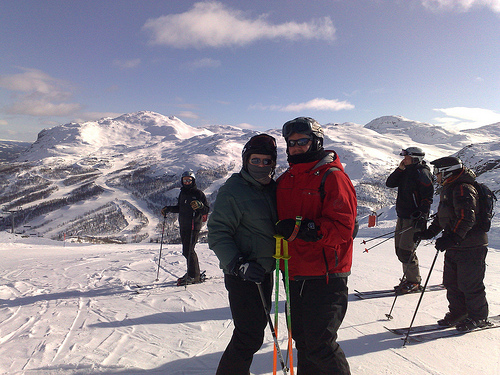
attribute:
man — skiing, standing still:
[275, 116, 357, 375]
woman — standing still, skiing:
[207, 132, 278, 374]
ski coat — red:
[275, 150, 358, 281]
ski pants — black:
[283, 277, 351, 375]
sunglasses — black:
[287, 137, 311, 147]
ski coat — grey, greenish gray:
[207, 170, 277, 272]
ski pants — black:
[216, 274, 273, 374]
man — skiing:
[413, 156, 489, 331]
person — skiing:
[385, 147, 436, 293]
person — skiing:
[161, 171, 209, 285]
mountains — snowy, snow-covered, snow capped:
[1, 109, 500, 241]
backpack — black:
[460, 179, 498, 233]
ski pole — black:
[402, 249, 440, 347]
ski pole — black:
[384, 237, 422, 320]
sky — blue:
[0, 1, 499, 144]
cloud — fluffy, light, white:
[139, 1, 339, 53]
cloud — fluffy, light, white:
[249, 96, 356, 111]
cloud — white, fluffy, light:
[4, 64, 81, 118]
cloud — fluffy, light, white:
[420, 0, 499, 16]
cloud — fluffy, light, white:
[112, 56, 143, 70]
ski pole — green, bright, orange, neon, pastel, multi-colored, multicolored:
[283, 238, 295, 374]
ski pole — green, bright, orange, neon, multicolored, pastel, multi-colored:
[271, 233, 286, 374]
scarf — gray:
[248, 162, 272, 183]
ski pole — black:
[156, 213, 167, 285]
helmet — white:
[403, 147, 426, 162]